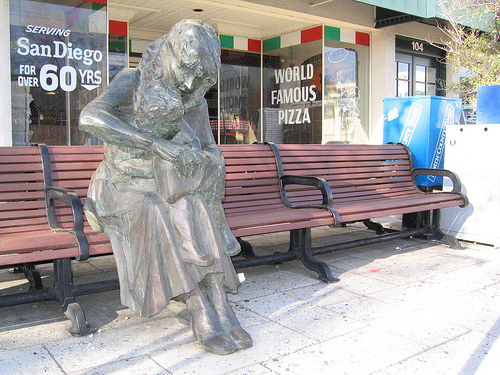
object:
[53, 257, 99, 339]
leg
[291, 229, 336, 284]
leg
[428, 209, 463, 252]
leg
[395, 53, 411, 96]
door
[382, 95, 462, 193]
dispenser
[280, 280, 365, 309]
tile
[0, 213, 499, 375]
sidewalk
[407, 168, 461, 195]
armrests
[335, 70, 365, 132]
sign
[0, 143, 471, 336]
benches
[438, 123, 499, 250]
box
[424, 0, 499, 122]
tree